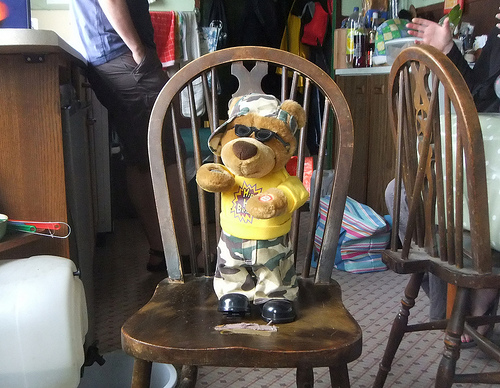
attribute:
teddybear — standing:
[198, 92, 310, 318]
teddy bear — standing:
[203, 80, 312, 323]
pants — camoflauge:
[213, 225, 304, 318]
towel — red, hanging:
[145, 12, 176, 69]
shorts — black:
[74, 44, 191, 214]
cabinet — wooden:
[371, 68, 418, 221]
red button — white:
[251, 185, 281, 210]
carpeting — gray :
[346, 274, 392, 316]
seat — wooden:
[101, 188, 391, 372]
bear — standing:
[194, 91, 311, 326]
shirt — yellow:
[214, 167, 308, 239]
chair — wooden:
[142, 51, 356, 340]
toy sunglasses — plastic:
[216, 109, 333, 144]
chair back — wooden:
[151, 55, 339, 282]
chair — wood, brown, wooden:
[117, 44, 367, 386]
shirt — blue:
[71, 0, 152, 60]